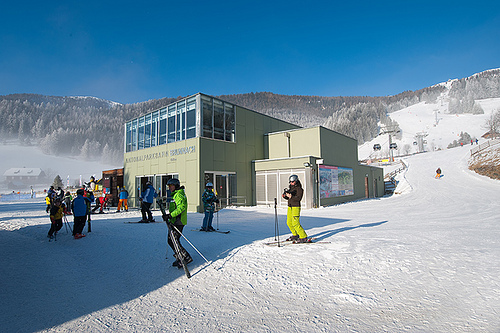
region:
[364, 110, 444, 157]
ski lift on snowy mountain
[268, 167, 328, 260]
woman in yellow ski pants ready to ski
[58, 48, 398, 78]
crystal clear blue skies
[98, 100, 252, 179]
ski lodge on mountain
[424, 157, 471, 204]
skier in bright orange coming down hill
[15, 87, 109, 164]
trees on side of mountain top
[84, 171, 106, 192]
blow up penguin at ski lodge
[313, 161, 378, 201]
map on side of building for ski hills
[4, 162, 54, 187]
building in background of ski lodge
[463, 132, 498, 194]
safety fence along ski trail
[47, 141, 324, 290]
people getting ready to go skiing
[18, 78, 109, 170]
mountains covered with green trees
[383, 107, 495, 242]
people coming down ski slope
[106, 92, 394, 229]
tan building at base of ski slope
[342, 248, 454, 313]
white snow covering the ground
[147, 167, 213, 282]
person carrying skies and ski poles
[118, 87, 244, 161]
tall glass windows on second floor of building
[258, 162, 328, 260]
person wearing yellow ski pants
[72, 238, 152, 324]
large shadow covering ground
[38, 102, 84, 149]
trees with a light layer of snow on them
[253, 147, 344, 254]
the skier has yellow pants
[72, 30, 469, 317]
people at the ski center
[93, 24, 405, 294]
the building is modern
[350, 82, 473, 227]
ski lifts in background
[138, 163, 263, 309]
the skier's jacket is green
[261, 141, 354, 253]
she has a silver helmet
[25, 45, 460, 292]
the sport is sking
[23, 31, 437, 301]
the season is winter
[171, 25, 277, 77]
the sky is clear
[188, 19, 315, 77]
the sky is blue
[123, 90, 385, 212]
a building in the snow.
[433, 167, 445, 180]
a skier on a hill.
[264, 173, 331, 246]
A snow skier in yellow.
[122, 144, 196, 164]
writing on a building.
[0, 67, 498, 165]
trees on a mountain.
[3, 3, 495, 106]
A bright blue sky.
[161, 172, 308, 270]
three people in the snow.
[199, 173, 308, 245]
two people in the snow.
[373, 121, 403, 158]
a ski lift for people.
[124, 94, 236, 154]
windows on a building.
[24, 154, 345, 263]
Many skiers in photo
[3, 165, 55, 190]
Log building in background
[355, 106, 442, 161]
Ski lift along slope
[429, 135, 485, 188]
Skiers coming down slope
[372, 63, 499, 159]
Trees along sides of slopes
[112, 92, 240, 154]
Large windows across top of building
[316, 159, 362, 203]
Large sign on side of building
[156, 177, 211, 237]
Skier wearing bright jacket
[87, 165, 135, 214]
Small brown building next to larger one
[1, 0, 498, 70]
Clear blue sky